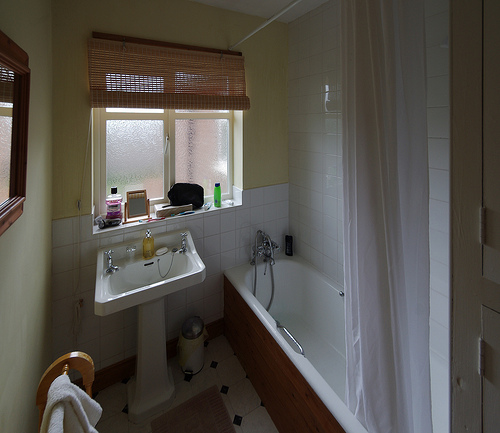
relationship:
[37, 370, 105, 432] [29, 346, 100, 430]
towel hanging from rack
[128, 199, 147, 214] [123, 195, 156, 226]
mirror sitting on stand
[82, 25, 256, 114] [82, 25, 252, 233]
blind covering window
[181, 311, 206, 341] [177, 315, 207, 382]
lid on garbage can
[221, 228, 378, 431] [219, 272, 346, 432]
bathtub with wood side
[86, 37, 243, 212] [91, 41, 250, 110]
window with bamboo shade